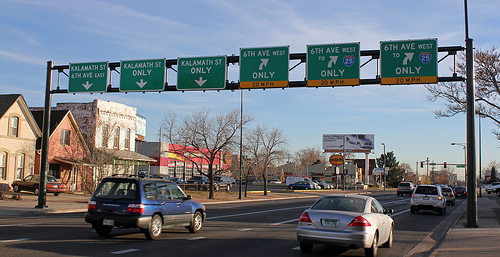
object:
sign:
[66, 63, 108, 93]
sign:
[117, 60, 166, 92]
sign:
[174, 54, 226, 93]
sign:
[237, 46, 289, 89]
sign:
[302, 42, 358, 88]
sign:
[380, 39, 440, 85]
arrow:
[81, 79, 96, 91]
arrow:
[132, 78, 148, 89]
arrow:
[194, 74, 210, 86]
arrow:
[255, 58, 271, 70]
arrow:
[397, 51, 415, 66]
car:
[84, 173, 206, 240]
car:
[296, 193, 398, 256]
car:
[406, 184, 446, 215]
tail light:
[85, 203, 103, 210]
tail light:
[127, 203, 147, 215]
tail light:
[297, 212, 314, 224]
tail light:
[343, 216, 374, 227]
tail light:
[408, 192, 420, 201]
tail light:
[437, 196, 443, 200]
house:
[0, 93, 43, 192]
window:
[9, 116, 23, 136]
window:
[0, 150, 8, 179]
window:
[14, 154, 32, 181]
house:
[28, 107, 93, 192]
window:
[59, 128, 73, 147]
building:
[30, 99, 145, 194]